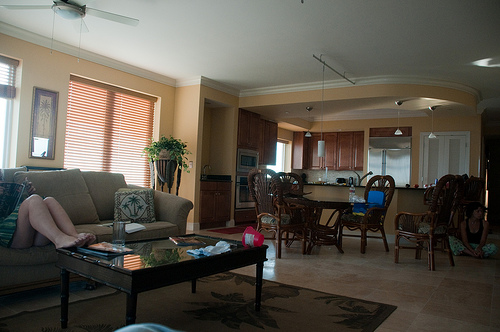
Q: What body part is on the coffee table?
A: Feet.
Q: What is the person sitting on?
A: On the couch.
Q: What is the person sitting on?
A: On the ground.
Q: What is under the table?
A: A carpet.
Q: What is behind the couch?
A: A window.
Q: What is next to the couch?
A: A plant.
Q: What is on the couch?
A: A pillow.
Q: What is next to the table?
A: A chair.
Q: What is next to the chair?
A: A table.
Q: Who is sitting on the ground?
A: A woman.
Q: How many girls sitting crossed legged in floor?
A: One.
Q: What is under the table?
A: A rug.